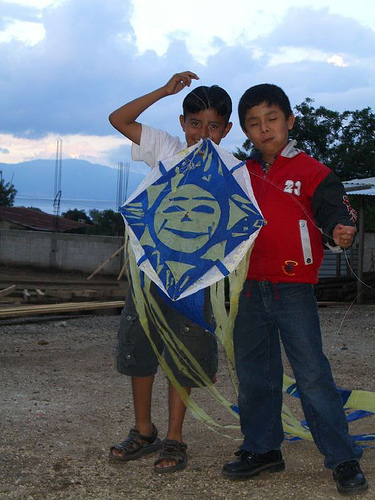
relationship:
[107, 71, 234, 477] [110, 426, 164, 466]
boy has sandal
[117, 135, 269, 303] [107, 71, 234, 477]
kite held by boy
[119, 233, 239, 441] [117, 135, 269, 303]
tail on kite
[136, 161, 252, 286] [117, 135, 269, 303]
sun on kite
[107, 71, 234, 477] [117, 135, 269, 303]
boy has a kite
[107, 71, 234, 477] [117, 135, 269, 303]
boy has kite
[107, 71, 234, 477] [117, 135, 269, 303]
boy holding kite